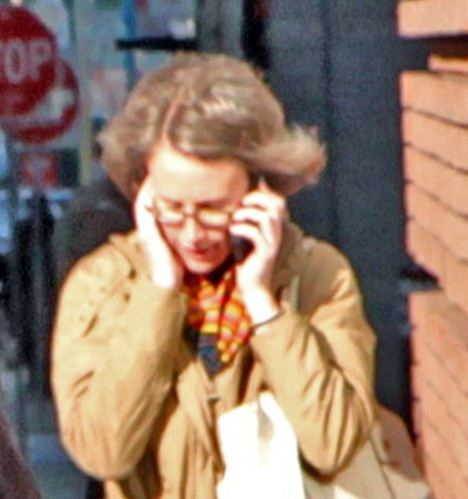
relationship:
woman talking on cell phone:
[48, 49, 377, 498] [227, 174, 276, 259]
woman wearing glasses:
[48, 49, 377, 498] [146, 194, 241, 232]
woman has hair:
[48, 49, 377, 498] [90, 57, 334, 208]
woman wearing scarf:
[48, 49, 377, 498] [175, 274, 262, 372]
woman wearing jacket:
[48, 49, 377, 498] [47, 232, 375, 498]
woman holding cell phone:
[48, 49, 377, 498] [227, 174, 276, 259]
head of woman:
[90, 57, 334, 208] [48, 49, 377, 498]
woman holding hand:
[48, 49, 377, 498] [131, 175, 185, 293]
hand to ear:
[131, 175, 185, 293] [135, 174, 146, 201]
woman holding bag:
[48, 57, 377, 488] [207, 386, 433, 499]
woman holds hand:
[48, 49, 377, 498] [135, 175, 186, 294]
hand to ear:
[135, 175, 186, 294] [140, 171, 149, 192]